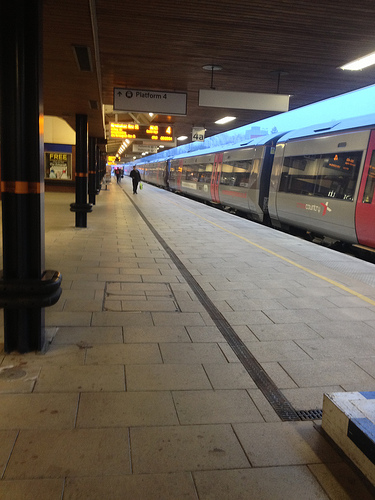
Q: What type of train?
A: Subway.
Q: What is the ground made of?
A: Brick.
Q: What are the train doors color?
A: Red.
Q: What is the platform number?
A: 4.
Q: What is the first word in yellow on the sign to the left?
A: Free.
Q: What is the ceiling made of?
A: Wood.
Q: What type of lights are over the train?
A: Fluorescent.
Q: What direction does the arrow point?
A: Up.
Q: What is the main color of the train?
A: Gray.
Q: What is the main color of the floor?
A: Gray.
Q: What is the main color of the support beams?
A: Black.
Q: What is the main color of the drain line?
A: Black.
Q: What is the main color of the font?
A: White.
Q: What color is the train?
A: Grey and red.